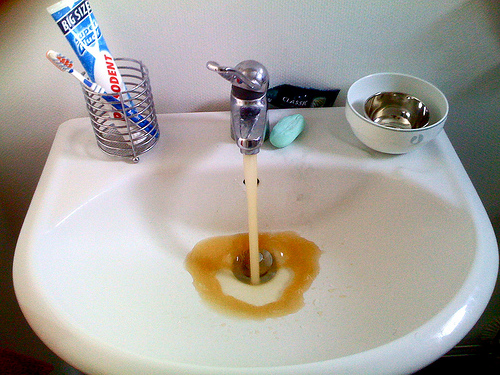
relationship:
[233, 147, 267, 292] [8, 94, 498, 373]
water coming out of sink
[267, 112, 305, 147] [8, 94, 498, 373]
soap on top of sink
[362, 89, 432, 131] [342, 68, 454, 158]
bowl inside bowl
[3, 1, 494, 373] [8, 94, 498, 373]
wall behind sink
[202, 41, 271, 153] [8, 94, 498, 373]
faucet on sink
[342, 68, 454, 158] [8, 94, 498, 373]
bowl on top of sink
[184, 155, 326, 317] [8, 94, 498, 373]
water in sink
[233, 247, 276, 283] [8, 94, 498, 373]
sink drain in a sink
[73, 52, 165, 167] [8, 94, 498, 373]
steel holder on a sink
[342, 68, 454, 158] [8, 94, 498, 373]
bowl on a sink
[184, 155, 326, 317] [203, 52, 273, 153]
water running from a faucet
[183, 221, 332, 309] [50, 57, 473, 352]
water pooling up in sink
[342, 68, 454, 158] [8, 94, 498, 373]
bowl on edge of sink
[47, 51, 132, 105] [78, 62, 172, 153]
toothbrush in holder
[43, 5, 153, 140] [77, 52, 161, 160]
tooth paste in holder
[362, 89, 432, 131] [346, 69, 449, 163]
bowl sitting in white dish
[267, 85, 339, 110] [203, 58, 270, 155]
paper behind faucet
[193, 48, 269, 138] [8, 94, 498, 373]
handle on sink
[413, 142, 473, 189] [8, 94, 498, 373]
wall on sink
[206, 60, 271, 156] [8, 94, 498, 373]
faucet on sink